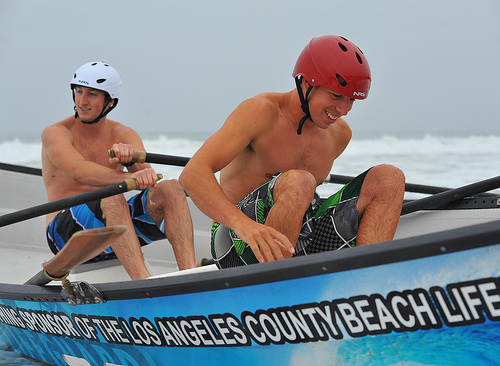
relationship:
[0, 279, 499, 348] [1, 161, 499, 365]
words on boat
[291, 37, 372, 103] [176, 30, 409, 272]
helmet on men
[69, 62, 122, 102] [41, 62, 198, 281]
helmet on man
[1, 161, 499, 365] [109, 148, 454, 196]
boat has an oar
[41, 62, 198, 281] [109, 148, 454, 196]
man holding oar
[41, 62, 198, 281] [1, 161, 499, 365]
man rowing boat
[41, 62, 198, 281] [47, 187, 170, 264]
man wearing swimming suit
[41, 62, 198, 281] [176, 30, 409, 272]
man behind men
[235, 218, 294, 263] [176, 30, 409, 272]
hand of men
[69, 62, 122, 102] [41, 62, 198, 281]
helmet worn by man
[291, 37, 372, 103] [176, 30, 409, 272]
helmet worn by men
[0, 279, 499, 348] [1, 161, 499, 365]
words on side of boat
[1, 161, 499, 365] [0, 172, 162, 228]
boat has an oar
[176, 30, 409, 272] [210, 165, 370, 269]
men wearing swimming suit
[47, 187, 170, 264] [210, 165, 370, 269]
swimming suit behind swimming suit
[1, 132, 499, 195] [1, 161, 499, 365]
waves behind boat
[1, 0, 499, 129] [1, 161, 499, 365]
sky above boat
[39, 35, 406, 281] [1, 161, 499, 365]
men rowing boat